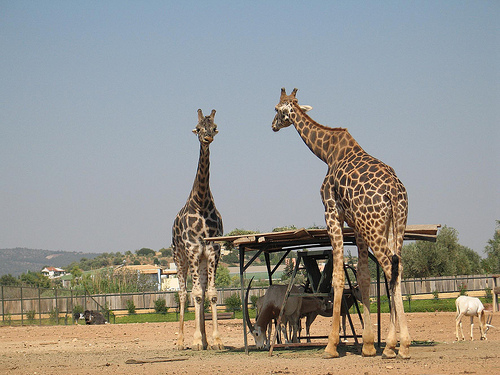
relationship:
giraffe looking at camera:
[174, 85, 242, 171] [0, 1, 492, 363]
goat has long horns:
[444, 284, 500, 340] [480, 319, 494, 335]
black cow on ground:
[78, 299, 127, 334] [77, 325, 151, 368]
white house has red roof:
[39, 268, 69, 281] [42, 265, 64, 274]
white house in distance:
[39, 268, 69, 281] [9, 208, 147, 301]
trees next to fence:
[62, 262, 182, 311] [10, 287, 196, 327]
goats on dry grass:
[223, 253, 373, 372] [216, 340, 341, 373]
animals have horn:
[223, 253, 373, 372] [233, 271, 264, 336]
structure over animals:
[211, 209, 457, 373] [223, 253, 373, 372]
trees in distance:
[62, 262, 182, 311] [9, 208, 147, 301]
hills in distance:
[9, 232, 100, 282] [6, 243, 177, 309]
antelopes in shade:
[228, 233, 386, 343] [210, 202, 468, 272]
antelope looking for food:
[444, 284, 500, 340] [472, 322, 500, 366]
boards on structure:
[210, 202, 468, 272] [211, 209, 457, 373]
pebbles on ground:
[36, 333, 118, 348] [9, 319, 168, 374]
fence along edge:
[10, 287, 196, 327] [20, 246, 488, 267]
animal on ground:
[64, 292, 129, 336] [9, 319, 168, 374]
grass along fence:
[3, 293, 500, 316] [10, 287, 196, 327]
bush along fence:
[28, 298, 110, 323] [10, 287, 196, 327]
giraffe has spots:
[174, 85, 242, 171] [189, 208, 226, 241]